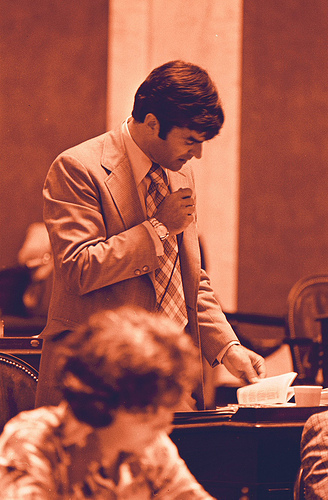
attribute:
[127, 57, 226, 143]
hair — brown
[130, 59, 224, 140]
hair — dark